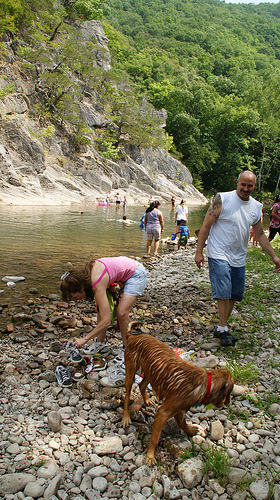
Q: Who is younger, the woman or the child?
A: The child is younger than the woman.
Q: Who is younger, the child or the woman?
A: The child is younger than the woman.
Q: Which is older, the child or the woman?
A: The woman is older than the child.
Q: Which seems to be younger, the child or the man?
A: The child is younger than the man.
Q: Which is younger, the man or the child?
A: The child is younger than the man.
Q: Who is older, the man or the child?
A: The man is older than the child.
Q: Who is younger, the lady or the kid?
A: The kid is younger than the lady.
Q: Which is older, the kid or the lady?
A: The lady is older than the kid.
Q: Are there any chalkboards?
A: No, there are no chalkboards.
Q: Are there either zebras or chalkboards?
A: No, there are no chalkboards or zebras.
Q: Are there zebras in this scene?
A: No, there are no zebras.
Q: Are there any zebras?
A: No, there are no zebras.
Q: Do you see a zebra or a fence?
A: No, there are no zebras or fences.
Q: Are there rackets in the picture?
A: No, there are no rackets.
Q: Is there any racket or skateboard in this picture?
A: No, there are no rackets or skateboards.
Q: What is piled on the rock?
A: The shoes are piled on the rock.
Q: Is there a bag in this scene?
A: No, there are no bags.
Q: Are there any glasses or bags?
A: No, there are no bags or glasses.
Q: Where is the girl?
A: The girl is in the water.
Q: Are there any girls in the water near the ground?
A: Yes, there is a girl in the water.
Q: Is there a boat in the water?
A: No, there is a girl in the water.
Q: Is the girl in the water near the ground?
A: Yes, the girl is in the water.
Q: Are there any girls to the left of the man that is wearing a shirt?
A: Yes, there is a girl to the left of the man.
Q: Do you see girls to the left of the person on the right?
A: Yes, there is a girl to the left of the man.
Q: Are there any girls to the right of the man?
A: No, the girl is to the left of the man.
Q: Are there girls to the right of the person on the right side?
A: No, the girl is to the left of the man.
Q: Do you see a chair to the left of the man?
A: No, there is a girl to the left of the man.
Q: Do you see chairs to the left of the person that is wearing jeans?
A: No, there is a girl to the left of the man.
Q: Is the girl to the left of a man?
A: Yes, the girl is to the left of a man.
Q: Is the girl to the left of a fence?
A: No, the girl is to the left of a man.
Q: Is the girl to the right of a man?
A: No, the girl is to the left of a man.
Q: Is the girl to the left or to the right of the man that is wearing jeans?
A: The girl is to the left of the man.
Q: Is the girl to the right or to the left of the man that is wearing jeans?
A: The girl is to the left of the man.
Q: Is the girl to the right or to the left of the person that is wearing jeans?
A: The girl is to the left of the man.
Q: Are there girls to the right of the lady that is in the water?
A: Yes, there is a girl to the right of the lady.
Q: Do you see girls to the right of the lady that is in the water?
A: Yes, there is a girl to the right of the lady.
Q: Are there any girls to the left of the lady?
A: No, the girl is to the right of the lady.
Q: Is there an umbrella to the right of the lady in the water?
A: No, there is a girl to the right of the lady.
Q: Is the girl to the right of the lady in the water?
A: Yes, the girl is to the right of the lady.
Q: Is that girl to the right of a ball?
A: No, the girl is to the right of the lady.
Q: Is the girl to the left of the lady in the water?
A: No, the girl is to the right of the lady.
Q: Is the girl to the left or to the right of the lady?
A: The girl is to the right of the lady.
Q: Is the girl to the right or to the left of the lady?
A: The girl is to the right of the lady.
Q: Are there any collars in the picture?
A: Yes, there is a collar.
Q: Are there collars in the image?
A: Yes, there is a collar.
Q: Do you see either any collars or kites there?
A: Yes, there is a collar.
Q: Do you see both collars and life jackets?
A: No, there is a collar but no life jackets.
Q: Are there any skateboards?
A: No, there are no skateboards.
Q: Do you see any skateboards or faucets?
A: No, there are no skateboards or faucets.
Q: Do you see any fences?
A: No, there are no fences.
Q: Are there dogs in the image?
A: Yes, there is a dog.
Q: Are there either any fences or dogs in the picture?
A: Yes, there is a dog.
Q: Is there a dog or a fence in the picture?
A: Yes, there is a dog.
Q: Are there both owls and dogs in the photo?
A: No, there is a dog but no owls.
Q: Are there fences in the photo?
A: No, there are no fences.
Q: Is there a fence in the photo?
A: No, there are no fences.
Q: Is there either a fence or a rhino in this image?
A: No, there are no fences or rhinos.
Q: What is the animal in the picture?
A: The animal is a dog.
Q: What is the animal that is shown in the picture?
A: The animal is a dog.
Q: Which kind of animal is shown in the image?
A: The animal is a dog.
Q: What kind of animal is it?
A: The animal is a dog.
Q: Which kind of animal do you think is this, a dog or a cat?
A: That is a dog.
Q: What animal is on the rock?
A: The dog is on the rock.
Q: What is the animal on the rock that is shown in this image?
A: The animal is a dog.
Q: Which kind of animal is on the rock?
A: The animal is a dog.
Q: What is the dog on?
A: The dog is on the rock.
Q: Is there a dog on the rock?
A: Yes, there is a dog on the rock.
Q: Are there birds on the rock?
A: No, there is a dog on the rock.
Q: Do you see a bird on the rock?
A: No, there is a dog on the rock.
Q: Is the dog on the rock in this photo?
A: Yes, the dog is on the rock.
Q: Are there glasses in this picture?
A: No, there are no glasses.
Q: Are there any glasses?
A: No, there are no glasses.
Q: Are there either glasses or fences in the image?
A: No, there are no glasses or fences.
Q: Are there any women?
A: Yes, there is a woman.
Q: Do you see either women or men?
A: Yes, there is a woman.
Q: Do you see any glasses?
A: No, there are no glasses.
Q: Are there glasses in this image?
A: No, there are no glasses.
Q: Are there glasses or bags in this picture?
A: No, there are no glasses or bags.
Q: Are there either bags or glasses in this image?
A: No, there are no glasses or bags.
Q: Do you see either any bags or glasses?
A: No, there are no glasses or bags.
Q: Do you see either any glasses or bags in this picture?
A: No, there are no glasses or bags.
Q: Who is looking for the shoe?
A: The woman is looking for the shoe.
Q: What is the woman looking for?
A: The woman is looking for the shoe.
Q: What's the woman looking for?
A: The woman is looking for the shoe.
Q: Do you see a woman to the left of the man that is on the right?
A: Yes, there is a woman to the left of the man.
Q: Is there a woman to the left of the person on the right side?
A: Yes, there is a woman to the left of the man.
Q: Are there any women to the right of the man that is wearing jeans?
A: No, the woman is to the left of the man.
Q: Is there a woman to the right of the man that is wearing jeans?
A: No, the woman is to the left of the man.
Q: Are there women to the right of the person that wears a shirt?
A: No, the woman is to the left of the man.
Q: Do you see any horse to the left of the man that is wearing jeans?
A: No, there is a woman to the left of the man.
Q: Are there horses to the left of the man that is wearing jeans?
A: No, there is a woman to the left of the man.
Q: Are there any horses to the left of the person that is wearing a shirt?
A: No, there is a woman to the left of the man.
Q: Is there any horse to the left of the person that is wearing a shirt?
A: No, there is a woman to the left of the man.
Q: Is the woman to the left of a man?
A: Yes, the woman is to the left of a man.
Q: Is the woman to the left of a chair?
A: No, the woman is to the left of a man.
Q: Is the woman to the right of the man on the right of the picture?
A: No, the woman is to the left of the man.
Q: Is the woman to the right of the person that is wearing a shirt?
A: No, the woman is to the left of the man.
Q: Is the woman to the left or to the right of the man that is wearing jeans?
A: The woman is to the left of the man.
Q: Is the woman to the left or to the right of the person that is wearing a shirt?
A: The woman is to the left of the man.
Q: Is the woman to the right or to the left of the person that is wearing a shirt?
A: The woman is to the left of the man.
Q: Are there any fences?
A: No, there are no fences.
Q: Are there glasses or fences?
A: No, there are no fences or glasses.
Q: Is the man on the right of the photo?
A: Yes, the man is on the right of the image.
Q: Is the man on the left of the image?
A: No, the man is on the right of the image.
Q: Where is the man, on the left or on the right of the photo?
A: The man is on the right of the image.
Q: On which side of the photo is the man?
A: The man is on the right of the image.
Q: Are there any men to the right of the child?
A: Yes, there is a man to the right of the child.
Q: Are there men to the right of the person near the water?
A: Yes, there is a man to the right of the child.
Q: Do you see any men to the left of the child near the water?
A: No, the man is to the right of the child.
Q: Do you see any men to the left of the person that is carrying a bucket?
A: No, the man is to the right of the child.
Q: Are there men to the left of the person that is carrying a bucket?
A: No, the man is to the right of the child.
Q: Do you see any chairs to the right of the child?
A: No, there is a man to the right of the child.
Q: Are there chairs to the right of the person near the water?
A: No, there is a man to the right of the child.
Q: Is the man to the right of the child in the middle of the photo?
A: Yes, the man is to the right of the child.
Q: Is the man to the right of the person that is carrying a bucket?
A: Yes, the man is to the right of the child.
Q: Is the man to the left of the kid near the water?
A: No, the man is to the right of the kid.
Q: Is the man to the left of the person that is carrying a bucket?
A: No, the man is to the right of the kid.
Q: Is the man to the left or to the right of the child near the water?
A: The man is to the right of the kid.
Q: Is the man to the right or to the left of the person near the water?
A: The man is to the right of the kid.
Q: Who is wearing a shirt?
A: The man is wearing a shirt.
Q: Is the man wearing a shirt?
A: Yes, the man is wearing a shirt.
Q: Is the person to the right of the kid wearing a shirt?
A: Yes, the man is wearing a shirt.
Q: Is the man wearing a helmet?
A: No, the man is wearing a shirt.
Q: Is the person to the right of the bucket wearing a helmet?
A: No, the man is wearing a shirt.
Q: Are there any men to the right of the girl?
A: Yes, there is a man to the right of the girl.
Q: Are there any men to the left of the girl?
A: No, the man is to the right of the girl.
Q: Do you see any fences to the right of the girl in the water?
A: No, there is a man to the right of the girl.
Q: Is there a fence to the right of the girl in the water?
A: No, there is a man to the right of the girl.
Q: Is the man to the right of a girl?
A: Yes, the man is to the right of a girl.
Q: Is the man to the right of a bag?
A: No, the man is to the right of a girl.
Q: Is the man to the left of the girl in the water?
A: No, the man is to the right of the girl.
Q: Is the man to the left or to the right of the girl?
A: The man is to the right of the girl.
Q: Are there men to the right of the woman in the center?
A: Yes, there is a man to the right of the woman.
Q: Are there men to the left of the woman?
A: No, the man is to the right of the woman.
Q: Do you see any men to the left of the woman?
A: No, the man is to the right of the woman.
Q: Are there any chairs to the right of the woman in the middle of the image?
A: No, there is a man to the right of the woman.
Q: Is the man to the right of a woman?
A: Yes, the man is to the right of a woman.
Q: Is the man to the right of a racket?
A: No, the man is to the right of a woman.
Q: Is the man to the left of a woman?
A: No, the man is to the right of a woman.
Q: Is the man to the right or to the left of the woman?
A: The man is to the right of the woman.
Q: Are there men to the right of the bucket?
A: Yes, there is a man to the right of the bucket.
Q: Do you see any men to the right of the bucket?
A: Yes, there is a man to the right of the bucket.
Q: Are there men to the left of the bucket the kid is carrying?
A: No, the man is to the right of the bucket.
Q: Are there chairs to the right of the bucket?
A: No, there is a man to the right of the bucket.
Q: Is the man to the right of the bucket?
A: Yes, the man is to the right of the bucket.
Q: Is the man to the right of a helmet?
A: No, the man is to the right of the bucket.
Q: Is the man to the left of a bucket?
A: No, the man is to the right of a bucket.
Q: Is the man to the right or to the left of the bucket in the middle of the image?
A: The man is to the right of the bucket.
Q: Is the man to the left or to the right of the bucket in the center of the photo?
A: The man is to the right of the bucket.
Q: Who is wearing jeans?
A: The man is wearing jeans.